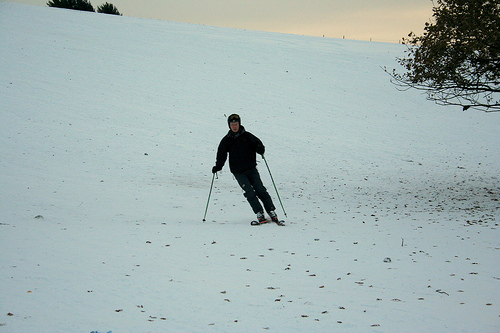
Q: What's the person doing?
A: Skiing.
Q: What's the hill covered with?
A: Snow.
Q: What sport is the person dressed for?
A: Skiing.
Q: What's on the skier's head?
A: Helmet.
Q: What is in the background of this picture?
A: Branches of a tree.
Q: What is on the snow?
A: Debris.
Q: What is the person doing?
A: Skiing down hill.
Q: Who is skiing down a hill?
A: A man.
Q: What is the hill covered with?
A: Snow.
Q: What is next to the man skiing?
A: A tree.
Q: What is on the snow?
A: Leaves.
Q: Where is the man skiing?
A: Down the hill.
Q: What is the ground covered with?
A: Snow.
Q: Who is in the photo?
A: Person skiing.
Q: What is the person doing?
A: Skiing.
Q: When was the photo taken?
A: Winter season.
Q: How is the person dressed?
A: In a black jacket and gray pants.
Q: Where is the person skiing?
A: On snow.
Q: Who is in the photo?
A: Skier.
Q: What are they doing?
A: Downhill skiing.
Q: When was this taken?
A: During the day.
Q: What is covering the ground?
A: Snow and leaves.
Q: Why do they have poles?
A: For balance.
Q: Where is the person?
A: On skis on the snow.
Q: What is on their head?
A: A hat.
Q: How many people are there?
A: One.